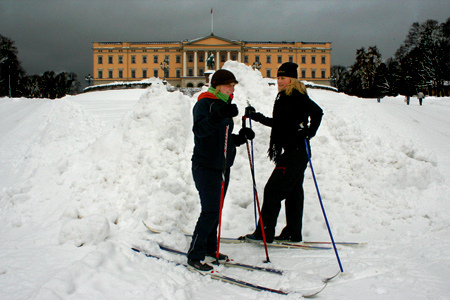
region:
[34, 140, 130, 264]
the snow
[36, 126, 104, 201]
the snow is white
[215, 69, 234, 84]
the hat the person is wearing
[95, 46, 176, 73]
a building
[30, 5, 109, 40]
the sky is dark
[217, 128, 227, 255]
person holding poles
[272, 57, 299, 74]
women wearing a black beanie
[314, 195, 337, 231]
a ski pole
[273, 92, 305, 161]
a black sweater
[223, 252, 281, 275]
skiis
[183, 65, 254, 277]
female skier wearing black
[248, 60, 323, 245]
female skier wearing black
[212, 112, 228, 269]
bright red ski pole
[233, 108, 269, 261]
bright red ski pole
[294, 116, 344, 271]
bright blue ski pole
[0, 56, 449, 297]
big pile of white snow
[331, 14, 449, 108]
grouping of tall trees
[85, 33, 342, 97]
large multi story tan building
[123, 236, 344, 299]
pair of skis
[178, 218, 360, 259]
a pair of skis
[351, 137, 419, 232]
the snow is white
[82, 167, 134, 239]
the snow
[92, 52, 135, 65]
windows on the building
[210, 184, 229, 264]
women is holding a red pole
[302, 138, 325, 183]
women is holding a blue pole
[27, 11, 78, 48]
the sky is dark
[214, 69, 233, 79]
person is wearing a hat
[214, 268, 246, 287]
person has a ski on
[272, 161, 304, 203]
the women is wearing black pants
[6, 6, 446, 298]
2 latest gears are saying here in front of a building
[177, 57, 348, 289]
the ladies are wearing warm black outfits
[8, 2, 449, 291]
what's piled up snow feels that the main part of the picture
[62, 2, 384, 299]
a capital looking structure tan in color. Rest in the background in the middle of the picture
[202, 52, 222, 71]
a small statue were sculptures seen in the background in front of the building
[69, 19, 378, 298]
the building consist of many windows in design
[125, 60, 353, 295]
these gears are wearing matching black toboggans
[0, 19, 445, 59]
the gray purple sky is the backdrop for this picture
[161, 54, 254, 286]
the latest gear, seen here, is wearing a scarf green and red in color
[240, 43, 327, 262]
a French black scarf drapes the neck of this lady skier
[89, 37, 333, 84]
the facade of a building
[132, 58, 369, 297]
two women on skis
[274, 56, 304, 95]
a woman wearing a ski cap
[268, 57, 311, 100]
a woman with blonde hair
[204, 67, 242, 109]
a woman with a black cap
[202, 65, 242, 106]
a woman with blonde hair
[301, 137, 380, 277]
a long blue ski pole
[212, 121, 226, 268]
a black and red ski pole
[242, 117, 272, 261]
a black and red ski pole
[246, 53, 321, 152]
a woman black jacket